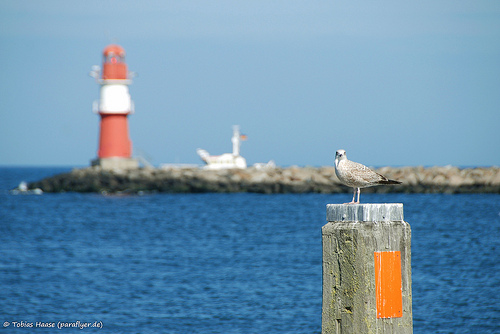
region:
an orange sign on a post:
[358, 230, 421, 332]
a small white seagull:
[315, 141, 414, 218]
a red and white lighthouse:
[80, 36, 150, 182]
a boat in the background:
[154, 113, 309, 191]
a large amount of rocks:
[51, 150, 489, 212]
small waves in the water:
[32, 226, 232, 321]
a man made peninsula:
[3, 138, 498, 204]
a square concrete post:
[286, 173, 443, 332]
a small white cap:
[10, 173, 35, 194]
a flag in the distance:
[229, 123, 264, 151]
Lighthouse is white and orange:
[87, 40, 144, 172]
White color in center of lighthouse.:
[93, 78, 133, 118]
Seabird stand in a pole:
[326, 143, 408, 205]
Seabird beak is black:
[328, 145, 407, 202]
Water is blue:
[0, 189, 334, 331]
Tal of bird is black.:
[375, 168, 407, 191]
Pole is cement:
[311, 196, 421, 331]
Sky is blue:
[0, 3, 497, 71]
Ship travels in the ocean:
[188, 121, 264, 174]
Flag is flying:
[234, 127, 254, 146]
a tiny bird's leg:
[355, 187, 362, 202]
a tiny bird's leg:
[351, 190, 356, 203]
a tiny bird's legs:
[343, 185, 362, 202]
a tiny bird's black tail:
[379, 170, 400, 188]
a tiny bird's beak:
[337, 151, 344, 160]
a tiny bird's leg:
[332, 145, 351, 162]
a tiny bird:
[331, 147, 401, 203]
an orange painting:
[371, 247, 403, 322]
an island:
[41, 160, 499, 194]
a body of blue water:
[8, 190, 493, 328]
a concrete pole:
[324, 200, 413, 332]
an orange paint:
[372, 246, 403, 319]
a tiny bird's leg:
[356, 186, 361, 205]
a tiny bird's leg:
[349, 187, 356, 202]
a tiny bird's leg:
[347, 183, 362, 203]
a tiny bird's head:
[332, 147, 347, 159]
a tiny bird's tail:
[377, 167, 401, 187]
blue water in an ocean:
[8, 193, 498, 323]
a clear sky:
[1, 2, 495, 162]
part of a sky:
[301, 46, 371, 89]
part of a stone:
[317, 255, 364, 310]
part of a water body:
[148, 212, 218, 258]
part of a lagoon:
[203, 162, 264, 202]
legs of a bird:
[343, 190, 356, 202]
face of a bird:
[333, 145, 351, 165]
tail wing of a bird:
[378, 169, 400, 194]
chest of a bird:
[323, 159, 358, 194]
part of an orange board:
[353, 252, 385, 294]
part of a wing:
[343, 161, 379, 191]